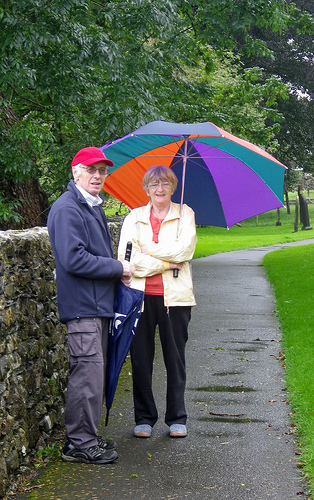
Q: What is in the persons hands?
A: Umbrella.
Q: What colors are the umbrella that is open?
A: Blue, orange, purple, green.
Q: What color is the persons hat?
A: Red.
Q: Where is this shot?
A: Sidewalk.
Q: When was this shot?
A: Daytime.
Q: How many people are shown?
A: 2.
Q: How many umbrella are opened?
A: 1.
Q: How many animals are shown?
A: 0.